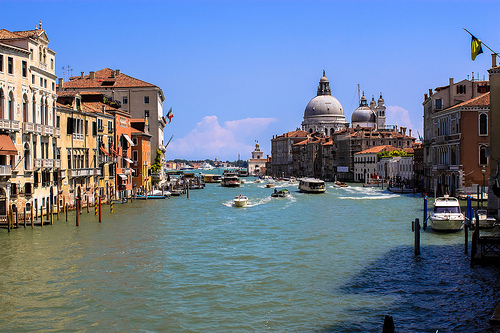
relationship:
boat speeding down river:
[229, 198, 249, 206] [122, 202, 350, 320]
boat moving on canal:
[229, 190, 249, 206] [102, 211, 370, 324]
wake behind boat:
[250, 197, 270, 204] [230, 195, 249, 211]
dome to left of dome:
[301, 69, 348, 128] [350, 94, 376, 125]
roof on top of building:
[60, 65, 160, 91] [54, 65, 163, 178]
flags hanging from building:
[167, 104, 175, 124] [60, 65, 163, 185]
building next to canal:
[58, 92, 112, 209] [3, 169, 473, 325]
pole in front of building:
[103, 179, 110, 205] [58, 88, 108, 204]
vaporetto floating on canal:
[296, 173, 328, 195] [3, 169, 473, 325]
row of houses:
[0, 28, 168, 225] [4, 20, 165, 219]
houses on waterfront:
[4, 20, 165, 219] [10, 182, 199, 227]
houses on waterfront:
[4, 20, 165, 219] [12, 190, 174, 230]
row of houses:
[8, 21, 168, 218] [4, 20, 165, 219]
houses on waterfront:
[4, 20, 165, 219] [11, 185, 176, 230]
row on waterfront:
[0, 28, 168, 225] [11, 183, 174, 233]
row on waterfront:
[0, 28, 168, 225] [8, 181, 169, 232]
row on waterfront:
[8, 21, 168, 218] [10, 177, 174, 232]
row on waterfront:
[8, 21, 168, 218] [28, 183, 173, 231]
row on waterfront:
[0, 28, 168, 225] [17, 165, 172, 233]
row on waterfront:
[0, 28, 168, 225] [10, 175, 173, 236]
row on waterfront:
[0, 28, 168, 225] [9, 170, 173, 232]